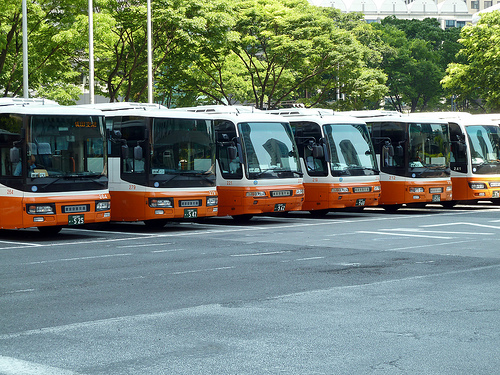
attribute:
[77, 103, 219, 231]
bus — orange, white, parked, here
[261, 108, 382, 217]
bus — parked, orange, white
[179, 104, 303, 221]
bus — parked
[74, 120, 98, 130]
sign — electronic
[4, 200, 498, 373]
lot — here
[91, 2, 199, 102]
tree — here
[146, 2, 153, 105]
pole — here, white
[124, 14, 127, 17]
leaf — green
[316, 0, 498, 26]
wall — here, white